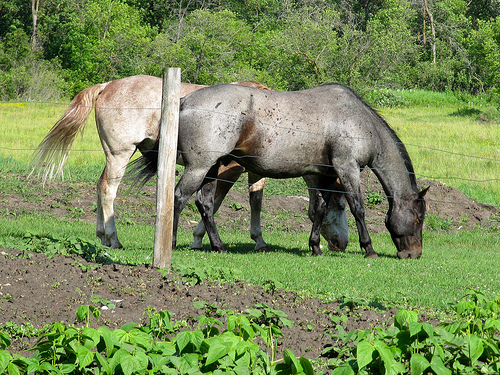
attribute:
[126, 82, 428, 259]
horse — grazing, dark, gray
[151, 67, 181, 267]
post — wooden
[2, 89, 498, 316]
grass — green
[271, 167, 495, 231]
dirt — mounded, black, tilled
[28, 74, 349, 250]
horse — light colored, gray, white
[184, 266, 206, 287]
plant — small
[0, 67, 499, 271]
fence — metal, wire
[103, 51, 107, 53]
leaf — green